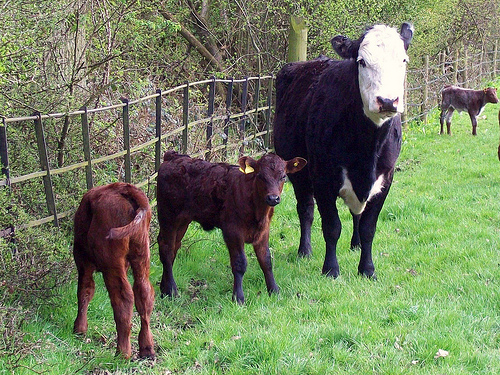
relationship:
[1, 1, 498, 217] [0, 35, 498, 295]
trees near fence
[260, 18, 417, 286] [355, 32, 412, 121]
cow has face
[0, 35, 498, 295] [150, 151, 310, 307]
fence behind calf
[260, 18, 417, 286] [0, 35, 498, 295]
cow in front of fence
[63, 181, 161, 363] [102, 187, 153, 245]
calf has tail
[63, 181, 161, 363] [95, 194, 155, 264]
cow has rear end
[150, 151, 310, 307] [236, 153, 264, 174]
calf has right ear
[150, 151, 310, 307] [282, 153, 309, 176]
calf has left ear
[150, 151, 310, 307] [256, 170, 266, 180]
calf has right eye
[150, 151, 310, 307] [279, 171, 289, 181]
calf has left eye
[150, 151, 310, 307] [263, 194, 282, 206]
calf has nose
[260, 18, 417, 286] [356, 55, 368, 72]
cow has right eye